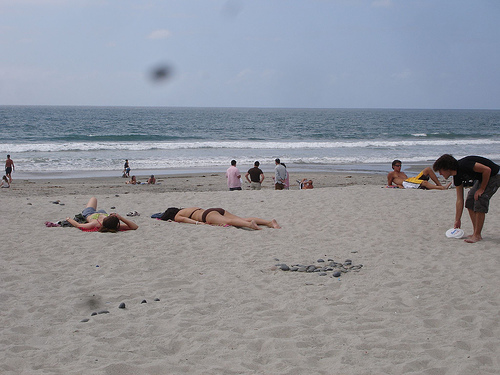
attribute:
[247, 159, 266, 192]
person — standing, watching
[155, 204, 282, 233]
lady — sun bathing, relaxing, lying down, tanning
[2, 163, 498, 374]
sand — soft, lumpy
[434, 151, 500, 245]
guy — young, bending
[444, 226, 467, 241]
frisbee — white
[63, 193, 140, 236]
person — laying down, tanning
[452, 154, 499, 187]
shirt — black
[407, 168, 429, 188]
shorts — yellow, black, white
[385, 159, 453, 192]
guy — laying down, lying down, shirtless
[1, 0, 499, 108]
sky — blue, clear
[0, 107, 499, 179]
water — calm, blue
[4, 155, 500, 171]
wave — washing up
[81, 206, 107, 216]
shorts — blue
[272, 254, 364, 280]
pile — small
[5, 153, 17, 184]
man — standing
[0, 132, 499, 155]
wave — breaking